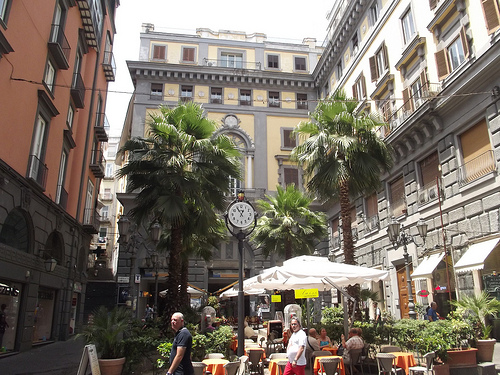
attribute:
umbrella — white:
[214, 231, 399, 309]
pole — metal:
[228, 226, 249, 371]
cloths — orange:
[384, 339, 416, 371]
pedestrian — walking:
[163, 312, 193, 374]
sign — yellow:
[293, 287, 320, 300]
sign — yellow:
[267, 290, 282, 302]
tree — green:
[108, 95, 250, 329]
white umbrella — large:
[216, 253, 391, 303]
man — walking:
[142, 309, 222, 373]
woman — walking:
[269, 313, 336, 363]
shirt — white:
[287, 331, 309, 363]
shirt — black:
[172, 330, 213, 372]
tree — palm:
[299, 90, 382, 266]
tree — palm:
[251, 187, 327, 247]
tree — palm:
[125, 104, 237, 314]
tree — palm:
[156, 197, 216, 299]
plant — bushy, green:
[71, 307, 141, 356]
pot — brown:
[93, 356, 126, 373]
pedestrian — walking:
[285, 315, 309, 374]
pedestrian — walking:
[160, 308, 194, 374]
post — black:
[382, 214, 432, 318]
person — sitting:
[163, 314, 193, 373]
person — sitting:
[285, 317, 307, 372]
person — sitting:
[339, 328, 365, 367]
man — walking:
[163, 311, 194, 373]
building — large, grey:
[116, 22, 332, 294]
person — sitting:
[305, 326, 320, 353]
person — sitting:
[316, 324, 332, 346]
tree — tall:
[110, 93, 259, 315]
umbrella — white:
[239, 237, 409, 318]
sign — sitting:
[74, 339, 104, 374]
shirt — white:
[284, 326, 310, 367]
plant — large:
[435, 319, 478, 371]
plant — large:
[448, 287, 498, 364]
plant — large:
[393, 315, 420, 351]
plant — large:
[417, 315, 444, 352]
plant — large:
[352, 315, 376, 340]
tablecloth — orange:
[388, 352, 418, 372]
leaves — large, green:
[183, 134, 243, 185]